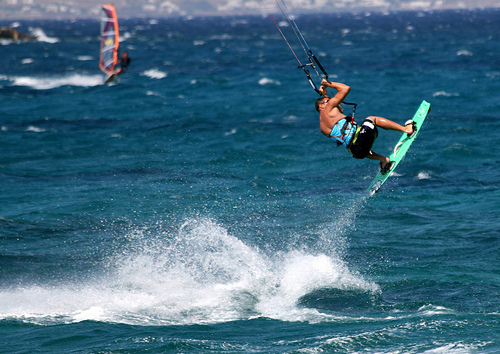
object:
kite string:
[257, 0, 309, 74]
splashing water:
[0, 158, 384, 329]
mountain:
[0, 24, 42, 44]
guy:
[314, 77, 415, 169]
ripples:
[0, 0, 500, 354]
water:
[0, 0, 500, 354]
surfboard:
[361, 99, 431, 202]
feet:
[403, 118, 413, 135]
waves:
[0, 189, 382, 328]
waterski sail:
[97, 2, 120, 75]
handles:
[297, 50, 329, 97]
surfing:
[312, 77, 432, 200]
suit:
[345, 118, 379, 159]